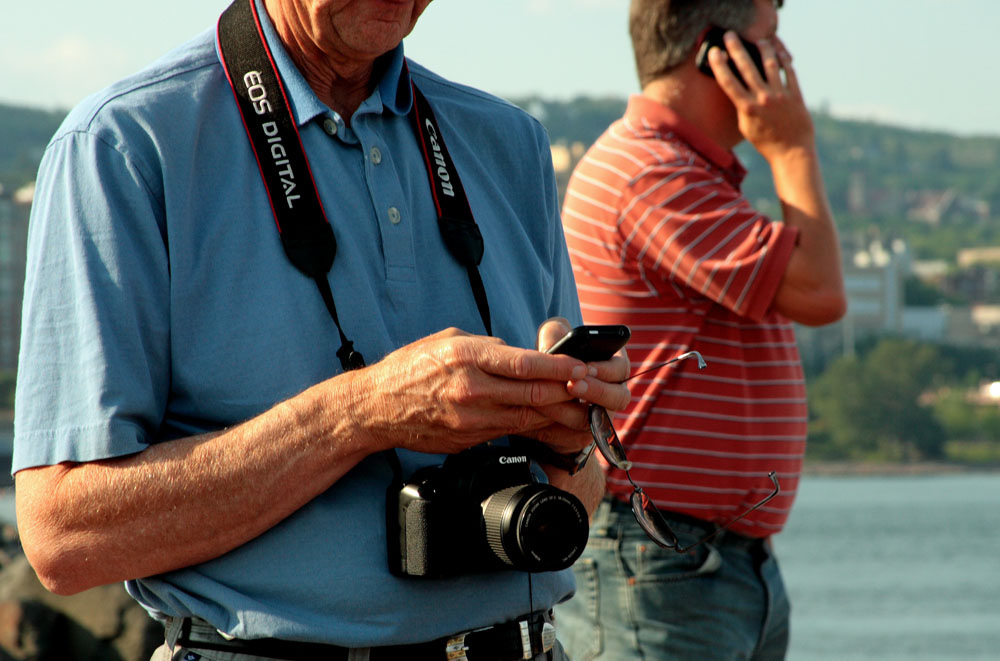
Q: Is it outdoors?
A: Yes, it is outdoors.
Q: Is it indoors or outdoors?
A: It is outdoors.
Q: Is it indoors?
A: No, it is outdoors.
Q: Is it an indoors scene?
A: No, it is outdoors.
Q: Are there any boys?
A: No, there are no boys.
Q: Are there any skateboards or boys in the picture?
A: No, there are no boys or skateboards.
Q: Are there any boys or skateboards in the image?
A: No, there are no boys or skateboards.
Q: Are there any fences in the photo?
A: No, there are no fences.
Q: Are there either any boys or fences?
A: No, there are no fences or boys.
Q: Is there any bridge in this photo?
A: No, there are no bridges.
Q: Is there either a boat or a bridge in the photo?
A: No, there are no bridges or boats.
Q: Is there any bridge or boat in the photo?
A: No, there are no bridges or boats.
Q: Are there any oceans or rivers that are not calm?
A: No, there is a river but it is calm.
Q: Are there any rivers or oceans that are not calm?
A: No, there is a river but it is calm.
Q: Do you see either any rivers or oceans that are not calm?
A: No, there is a river but it is calm.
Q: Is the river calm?
A: Yes, the river is calm.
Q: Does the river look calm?
A: Yes, the river is calm.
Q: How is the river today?
A: The river is calm.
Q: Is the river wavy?
A: No, the river is calm.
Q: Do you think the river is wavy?
A: No, the river is calm.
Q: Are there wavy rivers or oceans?
A: No, there is a river but it is calm.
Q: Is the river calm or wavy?
A: The river is calm.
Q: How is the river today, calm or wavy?
A: The river is calm.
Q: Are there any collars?
A: Yes, there is a collar.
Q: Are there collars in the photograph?
A: Yes, there is a collar.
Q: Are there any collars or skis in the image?
A: Yes, there is a collar.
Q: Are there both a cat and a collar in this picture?
A: No, there is a collar but no cats.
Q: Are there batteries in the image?
A: No, there are no batteries.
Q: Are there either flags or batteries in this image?
A: No, there are no batteries or flags.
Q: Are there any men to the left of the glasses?
A: Yes, there is a man to the left of the glasses.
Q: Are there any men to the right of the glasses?
A: No, the man is to the left of the glasses.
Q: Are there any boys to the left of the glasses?
A: No, there is a man to the left of the glasses.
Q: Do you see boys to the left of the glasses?
A: No, there is a man to the left of the glasses.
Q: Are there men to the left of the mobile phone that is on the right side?
A: Yes, there is a man to the left of the cellphone.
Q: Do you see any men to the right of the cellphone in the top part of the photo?
A: No, the man is to the left of the cellphone.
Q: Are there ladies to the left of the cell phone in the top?
A: No, there is a man to the left of the cell phone.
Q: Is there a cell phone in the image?
A: Yes, there is a cell phone.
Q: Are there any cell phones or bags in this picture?
A: Yes, there is a cell phone.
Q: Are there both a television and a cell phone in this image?
A: No, there is a cell phone but no televisions.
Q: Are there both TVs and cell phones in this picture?
A: No, there is a cell phone but no televisions.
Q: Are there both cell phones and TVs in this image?
A: No, there is a cell phone but no televisions.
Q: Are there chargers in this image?
A: No, there are no chargers.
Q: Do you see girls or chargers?
A: No, there are no chargers or girls.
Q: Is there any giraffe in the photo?
A: No, there are no giraffes.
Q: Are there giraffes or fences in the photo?
A: No, there are no giraffes or fences.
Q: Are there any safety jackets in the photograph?
A: No, there are no safety jackets.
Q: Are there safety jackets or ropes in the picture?
A: No, there are no safety jackets or ropes.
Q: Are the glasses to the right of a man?
A: Yes, the glasses are to the right of a man.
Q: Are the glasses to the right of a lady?
A: No, the glasses are to the right of a man.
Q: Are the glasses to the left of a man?
A: No, the glasses are to the right of a man.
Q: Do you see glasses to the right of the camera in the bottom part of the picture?
A: Yes, there are glasses to the right of the camera.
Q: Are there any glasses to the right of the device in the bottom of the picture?
A: Yes, there are glasses to the right of the camera.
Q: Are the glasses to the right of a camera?
A: Yes, the glasses are to the right of a camera.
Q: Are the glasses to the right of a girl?
A: No, the glasses are to the right of a camera.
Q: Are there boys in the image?
A: No, there are no boys.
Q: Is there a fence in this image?
A: No, there are no fences.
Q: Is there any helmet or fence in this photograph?
A: No, there are no fences or helmets.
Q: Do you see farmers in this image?
A: No, there are no farmers.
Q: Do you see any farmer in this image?
A: No, there are no farmers.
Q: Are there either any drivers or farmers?
A: No, there are no farmers or drivers.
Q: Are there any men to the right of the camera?
A: Yes, there is a man to the right of the camera.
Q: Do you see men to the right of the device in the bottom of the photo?
A: Yes, there is a man to the right of the camera.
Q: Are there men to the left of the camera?
A: No, the man is to the right of the camera.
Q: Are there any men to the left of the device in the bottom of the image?
A: No, the man is to the right of the camera.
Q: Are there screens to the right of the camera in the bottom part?
A: No, there is a man to the right of the camera.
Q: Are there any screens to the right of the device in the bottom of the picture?
A: No, there is a man to the right of the camera.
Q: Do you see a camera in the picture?
A: Yes, there is a camera.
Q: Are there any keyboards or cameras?
A: Yes, there is a camera.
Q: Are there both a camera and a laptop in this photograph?
A: No, there is a camera but no laptops.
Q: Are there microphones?
A: No, there are no microphones.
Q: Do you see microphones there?
A: No, there are no microphones.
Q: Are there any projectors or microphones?
A: No, there are no microphones or projectors.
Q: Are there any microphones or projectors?
A: No, there are no microphones or projectors.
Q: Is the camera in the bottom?
A: Yes, the camera is in the bottom of the image.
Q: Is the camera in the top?
A: No, the camera is in the bottom of the image.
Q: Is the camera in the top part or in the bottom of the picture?
A: The camera is in the bottom of the image.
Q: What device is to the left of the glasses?
A: The device is a camera.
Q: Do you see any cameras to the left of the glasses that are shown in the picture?
A: Yes, there is a camera to the left of the glasses.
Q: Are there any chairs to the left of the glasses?
A: No, there is a camera to the left of the glasses.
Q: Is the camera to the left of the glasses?
A: Yes, the camera is to the left of the glasses.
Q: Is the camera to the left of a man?
A: Yes, the camera is to the left of a man.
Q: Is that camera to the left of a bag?
A: No, the camera is to the left of a man.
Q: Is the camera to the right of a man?
A: No, the camera is to the left of a man.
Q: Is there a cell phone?
A: Yes, there is a cell phone.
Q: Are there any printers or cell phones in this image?
A: Yes, there is a cell phone.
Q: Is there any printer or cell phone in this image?
A: Yes, there is a cell phone.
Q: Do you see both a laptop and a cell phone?
A: No, there is a cell phone but no laptops.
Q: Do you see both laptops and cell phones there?
A: No, there is a cell phone but no laptops.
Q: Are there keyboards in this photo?
A: No, there are no keyboards.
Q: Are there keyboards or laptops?
A: No, there are no keyboards or laptops.